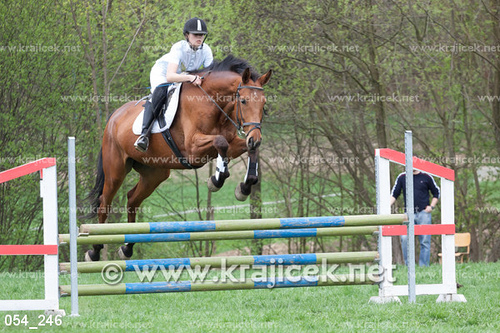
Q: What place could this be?
A: It is a field.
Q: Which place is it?
A: It is a field.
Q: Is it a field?
A: Yes, it is a field.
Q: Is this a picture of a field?
A: Yes, it is showing a field.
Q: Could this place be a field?
A: Yes, it is a field.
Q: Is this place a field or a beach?
A: It is a field.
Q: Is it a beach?
A: No, it is a field.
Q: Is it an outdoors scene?
A: Yes, it is outdoors.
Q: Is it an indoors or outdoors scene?
A: It is outdoors.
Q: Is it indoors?
A: No, it is outdoors.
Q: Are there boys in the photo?
A: No, there are no boys.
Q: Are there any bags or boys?
A: No, there are no boys or bags.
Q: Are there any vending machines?
A: No, there are no vending machines.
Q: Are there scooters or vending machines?
A: No, there are no vending machines or scooters.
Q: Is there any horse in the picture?
A: Yes, there is a horse.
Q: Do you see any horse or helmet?
A: Yes, there is a horse.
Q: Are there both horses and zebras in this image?
A: No, there is a horse but no zebras.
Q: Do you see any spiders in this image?
A: No, there are no spiders.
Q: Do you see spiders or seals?
A: No, there are no spiders or seals.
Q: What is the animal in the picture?
A: The animal is a horse.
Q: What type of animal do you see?
A: The animal is a horse.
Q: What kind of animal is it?
A: The animal is a horse.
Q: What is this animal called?
A: This is a horse.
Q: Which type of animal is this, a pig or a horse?
A: This is a horse.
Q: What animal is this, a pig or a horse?
A: This is a horse.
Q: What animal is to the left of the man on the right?
A: The animal is a horse.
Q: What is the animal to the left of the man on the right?
A: The animal is a horse.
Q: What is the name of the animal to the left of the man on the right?
A: The animal is a horse.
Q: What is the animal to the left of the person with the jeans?
A: The animal is a horse.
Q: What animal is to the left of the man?
A: The animal is a horse.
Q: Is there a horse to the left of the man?
A: Yes, there is a horse to the left of the man.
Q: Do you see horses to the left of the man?
A: Yes, there is a horse to the left of the man.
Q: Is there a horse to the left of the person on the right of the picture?
A: Yes, there is a horse to the left of the man.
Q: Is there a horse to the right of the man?
A: No, the horse is to the left of the man.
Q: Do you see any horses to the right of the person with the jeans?
A: No, the horse is to the left of the man.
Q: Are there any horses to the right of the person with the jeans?
A: No, the horse is to the left of the man.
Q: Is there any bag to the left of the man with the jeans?
A: No, there is a horse to the left of the man.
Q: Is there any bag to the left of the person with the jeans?
A: No, there is a horse to the left of the man.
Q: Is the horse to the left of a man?
A: Yes, the horse is to the left of a man.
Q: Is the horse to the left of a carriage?
A: No, the horse is to the left of a man.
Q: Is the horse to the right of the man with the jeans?
A: No, the horse is to the left of the man.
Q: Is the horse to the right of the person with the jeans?
A: No, the horse is to the left of the man.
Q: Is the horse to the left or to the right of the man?
A: The horse is to the left of the man.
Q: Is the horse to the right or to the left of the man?
A: The horse is to the left of the man.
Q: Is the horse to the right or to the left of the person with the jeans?
A: The horse is to the left of the man.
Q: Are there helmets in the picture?
A: Yes, there is a helmet.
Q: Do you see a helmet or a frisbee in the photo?
A: Yes, there is a helmet.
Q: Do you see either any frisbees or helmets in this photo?
A: Yes, there is a helmet.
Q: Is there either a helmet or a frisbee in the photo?
A: Yes, there is a helmet.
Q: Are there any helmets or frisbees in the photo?
A: Yes, there is a helmet.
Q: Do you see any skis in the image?
A: No, there are no skis.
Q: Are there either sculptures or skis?
A: No, there are no skis or sculptures.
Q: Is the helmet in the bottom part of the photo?
A: No, the helmet is in the top of the image.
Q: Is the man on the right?
A: Yes, the man is on the right of the image.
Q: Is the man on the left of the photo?
A: No, the man is on the right of the image.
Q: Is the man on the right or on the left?
A: The man is on the right of the image.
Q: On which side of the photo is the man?
A: The man is on the right of the image.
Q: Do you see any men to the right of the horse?
A: Yes, there is a man to the right of the horse.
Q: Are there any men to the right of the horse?
A: Yes, there is a man to the right of the horse.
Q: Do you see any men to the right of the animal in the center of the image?
A: Yes, there is a man to the right of the horse.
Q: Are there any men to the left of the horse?
A: No, the man is to the right of the horse.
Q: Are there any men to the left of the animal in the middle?
A: No, the man is to the right of the horse.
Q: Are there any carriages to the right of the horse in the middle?
A: No, there is a man to the right of the horse.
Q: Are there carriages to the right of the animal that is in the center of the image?
A: No, there is a man to the right of the horse.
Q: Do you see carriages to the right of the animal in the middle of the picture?
A: No, there is a man to the right of the horse.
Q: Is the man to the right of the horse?
A: Yes, the man is to the right of the horse.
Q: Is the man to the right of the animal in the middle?
A: Yes, the man is to the right of the horse.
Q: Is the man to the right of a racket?
A: No, the man is to the right of the horse.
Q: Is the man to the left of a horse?
A: No, the man is to the right of a horse.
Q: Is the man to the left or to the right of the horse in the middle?
A: The man is to the right of the horse.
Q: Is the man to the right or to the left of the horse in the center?
A: The man is to the right of the horse.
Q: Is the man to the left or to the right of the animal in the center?
A: The man is to the right of the horse.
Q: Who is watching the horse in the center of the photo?
A: The man is watching the horse.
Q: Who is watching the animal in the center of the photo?
A: The man is watching the horse.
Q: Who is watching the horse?
A: The man is watching the horse.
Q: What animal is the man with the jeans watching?
A: The man is watching the horse.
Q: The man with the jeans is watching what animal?
A: The man is watching the horse.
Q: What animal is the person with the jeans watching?
A: The man is watching the horse.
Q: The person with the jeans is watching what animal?
A: The man is watching the horse.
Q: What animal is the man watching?
A: The man is watching the horse.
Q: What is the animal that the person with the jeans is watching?
A: The animal is a horse.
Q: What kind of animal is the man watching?
A: The man is watching the horse.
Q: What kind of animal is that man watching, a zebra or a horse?
A: The man is watching a horse.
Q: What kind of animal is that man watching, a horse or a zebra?
A: The man is watching a horse.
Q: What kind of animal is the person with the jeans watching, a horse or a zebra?
A: The man is watching a horse.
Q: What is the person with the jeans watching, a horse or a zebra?
A: The man is watching a horse.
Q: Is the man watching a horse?
A: Yes, the man is watching a horse.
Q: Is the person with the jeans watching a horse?
A: Yes, the man is watching a horse.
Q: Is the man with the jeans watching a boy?
A: No, the man is watching a horse.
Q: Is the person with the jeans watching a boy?
A: No, the man is watching a horse.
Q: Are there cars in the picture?
A: No, there are no cars.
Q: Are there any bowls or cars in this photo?
A: No, there are no cars or bowls.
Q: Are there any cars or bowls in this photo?
A: No, there are no cars or bowls.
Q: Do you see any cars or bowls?
A: No, there are no cars or bowls.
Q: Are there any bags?
A: No, there are no bags.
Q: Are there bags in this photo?
A: No, there are no bags.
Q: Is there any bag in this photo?
A: No, there are no bags.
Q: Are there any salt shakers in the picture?
A: No, there are no salt shakers.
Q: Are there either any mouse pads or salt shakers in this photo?
A: No, there are no salt shakers or mouse pads.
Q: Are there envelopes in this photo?
A: No, there are no envelopes.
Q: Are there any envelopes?
A: No, there are no envelopes.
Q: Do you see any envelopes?
A: No, there are no envelopes.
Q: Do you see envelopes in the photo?
A: No, there are no envelopes.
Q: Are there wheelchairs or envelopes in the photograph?
A: No, there are no envelopes or wheelchairs.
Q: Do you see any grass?
A: Yes, there is grass.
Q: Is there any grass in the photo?
A: Yes, there is grass.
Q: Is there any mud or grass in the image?
A: Yes, there is grass.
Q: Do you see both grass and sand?
A: No, there is grass but no sand.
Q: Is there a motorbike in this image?
A: No, there are no motorcycles.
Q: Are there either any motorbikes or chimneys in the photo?
A: No, there are no motorbikes or chimneys.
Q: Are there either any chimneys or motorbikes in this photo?
A: No, there are no motorbikes or chimneys.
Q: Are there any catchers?
A: No, there are no catchers.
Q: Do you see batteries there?
A: No, there are no batteries.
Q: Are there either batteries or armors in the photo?
A: No, there are no batteries or armors.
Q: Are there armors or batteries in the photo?
A: No, there are no batteries or armors.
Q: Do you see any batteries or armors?
A: No, there are no batteries or armors.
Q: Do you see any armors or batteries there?
A: No, there are no batteries or armors.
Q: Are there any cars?
A: No, there are no cars.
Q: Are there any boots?
A: Yes, there are boots.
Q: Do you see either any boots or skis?
A: Yes, there are boots.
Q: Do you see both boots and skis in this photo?
A: No, there are boots but no skis.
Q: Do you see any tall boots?
A: Yes, there are tall boots.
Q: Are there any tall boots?
A: Yes, there are tall boots.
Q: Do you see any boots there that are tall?
A: Yes, there are boots that are tall.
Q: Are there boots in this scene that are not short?
A: Yes, there are tall boots.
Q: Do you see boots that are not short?
A: Yes, there are tall boots.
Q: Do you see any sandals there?
A: No, there are no sandals.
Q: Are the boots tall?
A: Yes, the boots are tall.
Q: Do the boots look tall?
A: Yes, the boots are tall.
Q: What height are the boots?
A: The boots are tall.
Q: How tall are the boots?
A: The boots are tall.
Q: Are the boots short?
A: No, the boots are tall.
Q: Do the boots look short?
A: No, the boots are tall.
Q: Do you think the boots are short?
A: No, the boots are tall.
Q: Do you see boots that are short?
A: No, there are boots but they are tall.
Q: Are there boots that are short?
A: No, there are boots but they are tall.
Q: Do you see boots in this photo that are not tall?
A: No, there are boots but they are tall.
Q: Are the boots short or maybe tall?
A: The boots are tall.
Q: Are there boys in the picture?
A: No, there are no boys.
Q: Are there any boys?
A: No, there are no boys.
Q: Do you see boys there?
A: No, there are no boys.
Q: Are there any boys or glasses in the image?
A: No, there are no boys or glasses.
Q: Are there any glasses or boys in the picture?
A: No, there are no boys or glasses.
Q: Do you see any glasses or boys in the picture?
A: No, there are no boys or glasses.